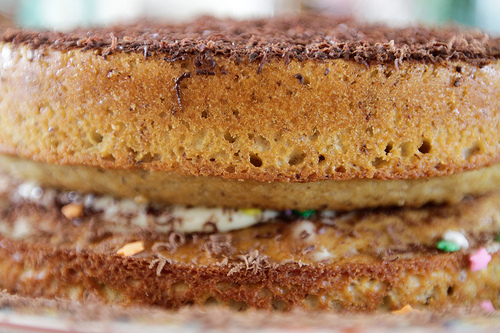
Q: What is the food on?
A: A plate.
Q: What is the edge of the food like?
A: Crispy.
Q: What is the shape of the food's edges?
A: Round.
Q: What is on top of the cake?
A: Frosting.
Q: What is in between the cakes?
A: Icing.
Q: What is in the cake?
A: Flakes.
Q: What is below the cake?
A: A plate.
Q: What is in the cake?
A: Holes.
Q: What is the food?
A: A dessert.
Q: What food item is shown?
A: Desert.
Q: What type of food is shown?
A: Cake.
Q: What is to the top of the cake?
A: Chocolate.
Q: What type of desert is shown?
A: Cake.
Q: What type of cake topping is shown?
A: Shaved chocolate.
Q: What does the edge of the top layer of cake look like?
A: Brown with holes.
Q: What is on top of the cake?
A: Grated chocolate.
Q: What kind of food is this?
A: Cake.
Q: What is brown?
A: Icing.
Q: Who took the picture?
A: Food critic.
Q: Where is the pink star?
A: To the right on the second layer.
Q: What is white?
A: Middle icing.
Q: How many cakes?
A: One.